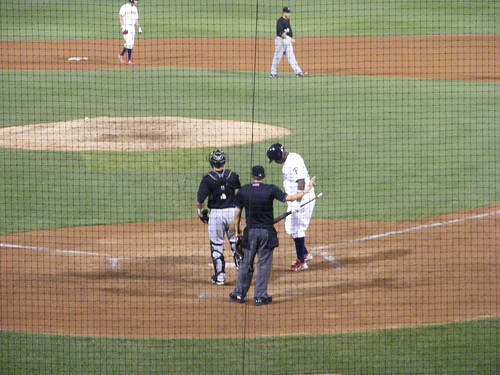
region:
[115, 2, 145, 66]
man is wearing baseball glove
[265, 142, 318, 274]
man is holding a bat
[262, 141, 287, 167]
man's helmet is black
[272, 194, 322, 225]
the bat is brown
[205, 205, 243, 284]
man's pants are gray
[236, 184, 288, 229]
man's shirt is black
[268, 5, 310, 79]
man wearing a hat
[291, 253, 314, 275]
man's shoes are red and white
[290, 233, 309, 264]
man's socks are black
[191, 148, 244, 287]
man wearing baseball glove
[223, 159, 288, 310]
umpiren at a game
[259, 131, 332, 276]
batter at home plate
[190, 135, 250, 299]
catcher at a baseball game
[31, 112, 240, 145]
pitcher's mound at a baseball field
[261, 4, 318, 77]
player at a baseball game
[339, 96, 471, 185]
green grass at a field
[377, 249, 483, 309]
dirt ground of a baseball field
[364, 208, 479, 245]
white chalk line on a field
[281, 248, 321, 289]
cleats on a baseball player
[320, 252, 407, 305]
shadows on the ground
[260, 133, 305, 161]
head of a person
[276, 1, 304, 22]
head of a person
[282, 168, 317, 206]
arm of a person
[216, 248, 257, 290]
leg of a person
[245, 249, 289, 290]
leg of a person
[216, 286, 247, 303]
feet of a person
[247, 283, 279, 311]
feet of a person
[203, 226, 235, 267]
leg of a person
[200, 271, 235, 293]
feet of a person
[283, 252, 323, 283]
feet of a person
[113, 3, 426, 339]
Players on the field.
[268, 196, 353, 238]
The player is holding a bat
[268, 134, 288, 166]
The man is wearing a helmet.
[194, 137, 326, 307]
Three players on home plate.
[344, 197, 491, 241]
White line in the field.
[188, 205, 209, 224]
The catcher has glove on hand.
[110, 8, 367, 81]
Two players in the field.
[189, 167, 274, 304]
The umpire is behind the catcher.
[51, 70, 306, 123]
The field is green.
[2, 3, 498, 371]
black baseball field fence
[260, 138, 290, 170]
black helmet on batter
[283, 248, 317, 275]
pair of sneakers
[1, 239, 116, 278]
white line drawn on baseball field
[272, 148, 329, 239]
white baseball uniform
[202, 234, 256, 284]
knee and shin guard protectors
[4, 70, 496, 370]
green grass on baseball field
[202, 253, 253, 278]
white baseball diamond on ground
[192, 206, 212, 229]
black catcher's mitt